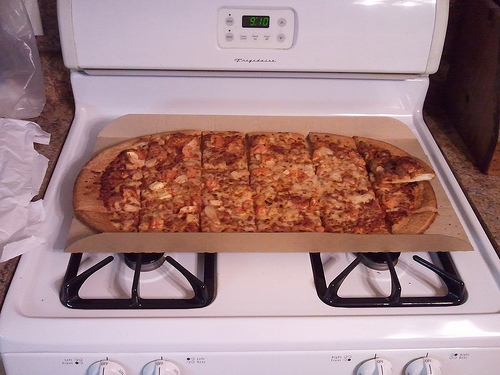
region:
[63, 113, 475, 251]
Baked pizza resting in cardboard platter on stove.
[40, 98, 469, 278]
pizza on a cardboard box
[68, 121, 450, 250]
oblong pizza cut into squares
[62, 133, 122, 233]
brown crust on the pizza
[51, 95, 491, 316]
pizza sitting on the stovetop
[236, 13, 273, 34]
digital clock on the stove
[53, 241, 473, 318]
two black burners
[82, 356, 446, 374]
row of four white knobs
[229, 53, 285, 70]
black Frigidare logo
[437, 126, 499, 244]
granite countertop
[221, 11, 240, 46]
two gray buttons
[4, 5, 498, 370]
pizza on cardboard on white stove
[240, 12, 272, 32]
digital clock on stove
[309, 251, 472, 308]
gas stove burner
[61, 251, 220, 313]
gas stove burner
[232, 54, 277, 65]
Frigidaire logo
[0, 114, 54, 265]
white plastic bag on countertop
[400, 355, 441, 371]
white stove burner knob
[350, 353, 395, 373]
white stove burner knob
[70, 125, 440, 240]
oval tomato pizza cut into slices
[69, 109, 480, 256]
brown cardboard under pizza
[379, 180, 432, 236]
a slice of pizza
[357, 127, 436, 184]
a slice of pizza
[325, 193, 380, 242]
a slice of pizza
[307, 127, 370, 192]
a slice of pizza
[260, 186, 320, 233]
a slice of pizza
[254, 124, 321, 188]
a slice of pizza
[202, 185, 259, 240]
a slice of pizza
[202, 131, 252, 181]
a slice of pizza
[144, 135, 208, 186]
a slice of pizza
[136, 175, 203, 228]
a slice of pizza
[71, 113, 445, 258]
large oval-shaped pizza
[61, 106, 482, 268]
pizza sitting on piece of cardboard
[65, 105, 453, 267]
chicken pizza with red sauce and cheese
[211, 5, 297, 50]
small white control panel on stove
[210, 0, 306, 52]
small white oven control panel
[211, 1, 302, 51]
control panel with digital clock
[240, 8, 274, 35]
digital clock and timer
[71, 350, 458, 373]
knobs for gas burners on stove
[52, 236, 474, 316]
metal grates for gas burners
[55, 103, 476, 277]
cardboard and pizza sitting on gas stove